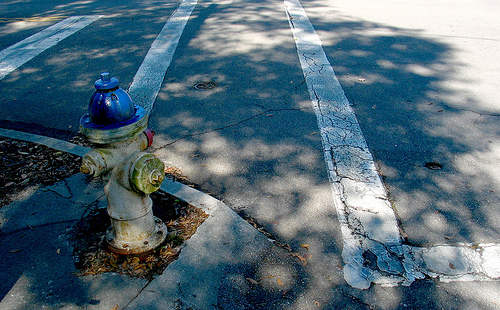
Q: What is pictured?
A: A fire hydrant.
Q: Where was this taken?
A: The side of the road.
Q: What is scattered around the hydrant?
A: Dried leaves.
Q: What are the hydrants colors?
A: Yellow and blue.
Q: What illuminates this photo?
A: Natural sunlight.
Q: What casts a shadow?
A: The trees behind the hydrant.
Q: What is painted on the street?
A: White traffic lines.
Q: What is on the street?
A: Shadow.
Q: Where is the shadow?
A: On the street.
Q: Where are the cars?
A: None in the photo.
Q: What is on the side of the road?
A: A hydrant.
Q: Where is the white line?
A: On street.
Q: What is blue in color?
A: Top of the hydrant.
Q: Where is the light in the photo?
A: Top right corner.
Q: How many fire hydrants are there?
A: One.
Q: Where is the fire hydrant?
A: Curb.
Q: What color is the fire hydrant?
A: Yellow.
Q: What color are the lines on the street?
A: White.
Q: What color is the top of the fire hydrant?
A: Blue.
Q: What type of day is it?
A: Sunny.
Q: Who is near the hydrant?
A: No one.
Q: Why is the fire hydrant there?
A: For emergency.